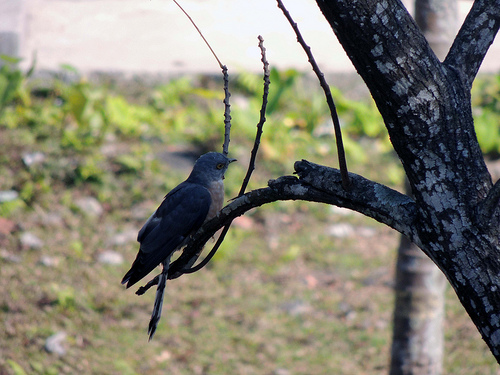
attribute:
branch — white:
[224, 12, 425, 215]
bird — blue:
[141, 142, 240, 347]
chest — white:
[208, 195, 219, 221]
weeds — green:
[1, 57, 498, 268]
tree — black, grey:
[136, 1, 498, 364]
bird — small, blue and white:
[121, 148, 245, 334]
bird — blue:
[121, 149, 240, 286]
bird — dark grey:
[120, 144, 235, 336]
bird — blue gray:
[134, 144, 275, 262]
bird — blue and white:
[147, 139, 248, 264]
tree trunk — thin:
[387, 3, 469, 374]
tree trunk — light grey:
[305, 1, 498, 372]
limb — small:
[447, 0, 498, 62]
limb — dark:
[329, 3, 451, 183]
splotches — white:
[394, 76, 466, 224]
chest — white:
[207, 177, 225, 215]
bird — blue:
[111, 138, 241, 346]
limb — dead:
[139, 156, 415, 295]